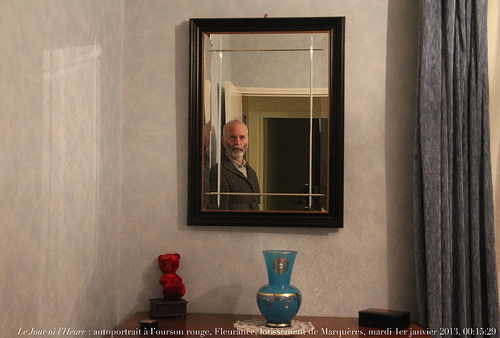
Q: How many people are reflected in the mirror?
A: One.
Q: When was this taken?
A: During the day.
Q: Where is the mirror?
A: On the wall.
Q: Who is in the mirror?
A: The man.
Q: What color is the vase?
A: Blue.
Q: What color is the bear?
A: Red.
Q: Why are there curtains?
A: Privacy.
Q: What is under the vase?
A: Doily.